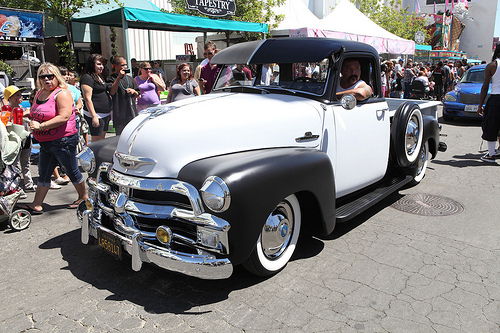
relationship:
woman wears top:
[32, 52, 109, 234] [28, 90, 78, 140]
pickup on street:
[87, 38, 442, 283] [0, 81, 498, 330]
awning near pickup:
[68, 0, 268, 37] [87, 38, 442, 283]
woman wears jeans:
[32, 52, 109, 234] [37, 140, 87, 185]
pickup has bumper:
[87, 38, 442, 283] [76, 166, 230, 280]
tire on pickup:
[394, 106, 424, 164] [87, 38, 442, 283]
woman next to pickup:
[32, 52, 109, 234] [87, 38, 442, 283]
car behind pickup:
[446, 60, 499, 119] [87, 38, 442, 283]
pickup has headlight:
[87, 38, 442, 283] [198, 178, 229, 215]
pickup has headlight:
[87, 38, 442, 283] [74, 145, 95, 173]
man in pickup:
[337, 58, 374, 101] [87, 38, 442, 283]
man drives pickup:
[337, 58, 374, 101] [87, 38, 442, 283]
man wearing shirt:
[108, 55, 135, 137] [106, 66, 139, 118]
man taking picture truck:
[108, 55, 135, 137] [79, 31, 448, 284]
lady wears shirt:
[165, 60, 204, 105] [165, 77, 201, 101]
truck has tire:
[108, 34, 448, 277] [382, 92, 440, 177]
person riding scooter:
[415, 70, 435, 95] [400, 73, 444, 113]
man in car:
[337, 58, 374, 101] [77, 37, 437, 287]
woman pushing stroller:
[32, 52, 109, 234] [2, 105, 41, 253]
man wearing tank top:
[474, 44, 499, 163] [488, 58, 499, 93]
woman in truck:
[124, 54, 164, 129] [94, 46, 460, 289]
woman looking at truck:
[124, 54, 164, 129] [94, 46, 460, 289]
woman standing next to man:
[77, 51, 121, 171] [109, 46, 134, 120]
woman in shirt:
[77, 51, 121, 171] [79, 70, 117, 112]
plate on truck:
[91, 227, 125, 257] [52, 30, 450, 274]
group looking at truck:
[82, 39, 246, 134] [79, 31, 448, 284]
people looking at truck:
[19, 40, 255, 164] [79, 31, 448, 284]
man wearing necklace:
[108, 55, 135, 137] [115, 75, 130, 90]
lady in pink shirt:
[15, 60, 90, 217] [27, 85, 79, 144]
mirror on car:
[339, 90, 359, 112] [66, 31, 458, 293]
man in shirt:
[108, 55, 135, 137] [104, 72, 137, 123]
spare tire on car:
[392, 99, 423, 169] [77, 37, 437, 287]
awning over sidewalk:
[68, 0, 268, 37] [106, 130, 115, 140]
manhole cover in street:
[395, 184, 470, 226] [276, 171, 490, 330]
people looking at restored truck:
[87, 55, 194, 95] [82, 37, 444, 278]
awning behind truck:
[68, 0, 268, 37] [79, 31, 448, 284]